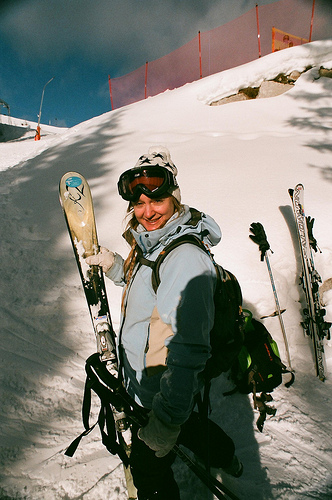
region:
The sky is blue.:
[9, 10, 95, 74]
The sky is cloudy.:
[16, 11, 105, 70]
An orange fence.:
[99, 18, 300, 116]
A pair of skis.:
[277, 179, 329, 400]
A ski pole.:
[242, 212, 304, 385]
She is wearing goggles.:
[113, 158, 192, 238]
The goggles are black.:
[107, 150, 193, 242]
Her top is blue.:
[94, 195, 242, 434]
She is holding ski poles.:
[80, 351, 248, 498]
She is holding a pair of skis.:
[42, 153, 158, 499]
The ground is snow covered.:
[188, 121, 278, 183]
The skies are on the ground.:
[267, 184, 330, 317]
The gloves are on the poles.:
[231, 214, 304, 380]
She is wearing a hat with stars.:
[108, 135, 212, 258]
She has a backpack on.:
[198, 249, 310, 411]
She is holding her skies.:
[53, 155, 163, 478]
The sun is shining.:
[27, 120, 299, 499]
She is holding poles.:
[74, 353, 258, 498]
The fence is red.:
[100, 59, 302, 100]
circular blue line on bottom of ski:
[57, 171, 94, 194]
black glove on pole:
[243, 219, 280, 271]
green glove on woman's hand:
[128, 415, 189, 454]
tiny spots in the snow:
[61, 456, 97, 467]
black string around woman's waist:
[46, 390, 130, 448]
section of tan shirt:
[147, 330, 164, 363]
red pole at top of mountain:
[31, 123, 53, 145]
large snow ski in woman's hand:
[50, 176, 124, 339]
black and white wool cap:
[128, 147, 183, 185]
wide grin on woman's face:
[118, 187, 220, 239]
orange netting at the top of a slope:
[99, 2, 329, 108]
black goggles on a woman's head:
[118, 161, 177, 201]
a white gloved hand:
[85, 232, 118, 271]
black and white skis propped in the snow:
[279, 179, 329, 375]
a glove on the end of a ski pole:
[244, 215, 277, 253]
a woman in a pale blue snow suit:
[112, 159, 274, 492]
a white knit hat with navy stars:
[130, 135, 185, 201]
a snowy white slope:
[0, 40, 331, 494]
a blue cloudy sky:
[3, 3, 327, 126]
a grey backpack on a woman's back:
[209, 259, 249, 381]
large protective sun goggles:
[117, 170, 168, 194]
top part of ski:
[60, 172, 104, 227]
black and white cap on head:
[136, 151, 180, 163]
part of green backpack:
[236, 304, 290, 386]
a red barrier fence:
[120, 54, 188, 82]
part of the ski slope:
[222, 134, 305, 178]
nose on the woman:
[142, 205, 161, 221]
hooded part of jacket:
[185, 212, 226, 241]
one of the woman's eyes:
[149, 199, 167, 207]